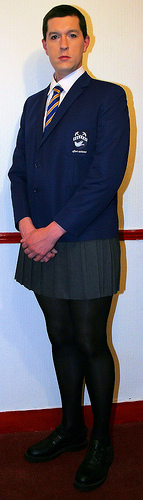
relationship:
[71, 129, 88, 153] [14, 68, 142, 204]
patch on blazer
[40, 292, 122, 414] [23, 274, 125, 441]
pantyhose on legs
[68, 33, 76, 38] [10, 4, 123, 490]
eye on man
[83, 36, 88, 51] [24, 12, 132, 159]
ear on man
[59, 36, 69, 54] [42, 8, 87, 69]
nose on face